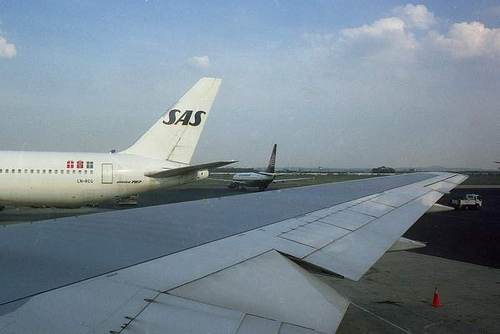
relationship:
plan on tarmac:
[227, 135, 287, 190] [184, 164, 495, 273]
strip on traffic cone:
[433, 290, 439, 296] [426, 286, 443, 308]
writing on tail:
[161, 106, 205, 125] [113, 68, 233, 172]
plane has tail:
[1, 52, 243, 212] [113, 68, 233, 172]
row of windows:
[2, 159, 102, 186] [1, 165, 94, 175]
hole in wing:
[275, 239, 358, 307] [3, 169, 467, 334]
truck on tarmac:
[452, 190, 484, 215] [184, 164, 495, 273]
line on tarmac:
[349, 300, 426, 333] [184, 164, 495, 273]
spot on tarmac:
[373, 297, 408, 309] [184, 164, 495, 273]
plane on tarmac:
[1, 52, 243, 212] [184, 164, 495, 273]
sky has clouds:
[2, 4, 498, 179] [313, 8, 497, 76]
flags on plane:
[63, 158, 96, 172] [1, 52, 243, 212]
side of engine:
[151, 174, 206, 193] [146, 150, 215, 191]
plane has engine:
[1, 52, 243, 212] [146, 150, 215, 191]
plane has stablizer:
[1, 52, 243, 212] [97, 188, 147, 205]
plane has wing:
[1, 52, 243, 212] [144, 161, 238, 178]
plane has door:
[1, 52, 243, 212] [96, 157, 119, 190]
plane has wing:
[1, 52, 243, 212] [147, 148, 235, 183]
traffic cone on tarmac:
[426, 286, 443, 308] [184, 164, 495, 273]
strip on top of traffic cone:
[433, 290, 439, 296] [426, 286, 443, 308]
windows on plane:
[1, 165, 94, 175] [1, 52, 243, 212]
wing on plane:
[147, 148, 235, 183] [1, 52, 243, 212]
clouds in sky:
[313, 8, 497, 76] [2, 4, 498, 179]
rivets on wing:
[103, 283, 185, 333] [3, 169, 467, 334]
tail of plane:
[113, 68, 233, 172] [1, 52, 243, 212]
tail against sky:
[113, 68, 233, 172] [2, 4, 498, 179]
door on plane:
[96, 157, 119, 190] [1, 52, 243, 212]